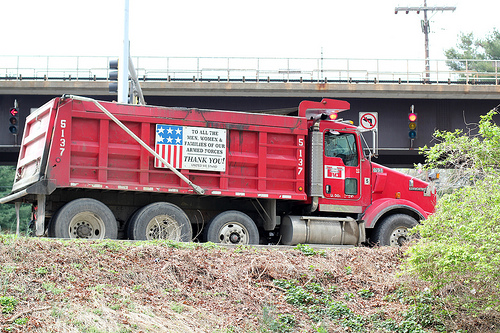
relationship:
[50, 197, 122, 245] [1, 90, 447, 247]
tire on truck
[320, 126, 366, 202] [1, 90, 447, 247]
door on truck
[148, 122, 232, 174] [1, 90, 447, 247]
sign on side of truck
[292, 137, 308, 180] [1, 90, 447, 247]
numbers on side of truck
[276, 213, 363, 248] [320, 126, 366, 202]
tank under door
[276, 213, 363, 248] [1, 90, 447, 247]
tank on side of truck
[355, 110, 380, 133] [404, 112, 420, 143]
sign near signal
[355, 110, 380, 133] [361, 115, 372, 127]
sign has black arrow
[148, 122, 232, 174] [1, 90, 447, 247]
sign on truck